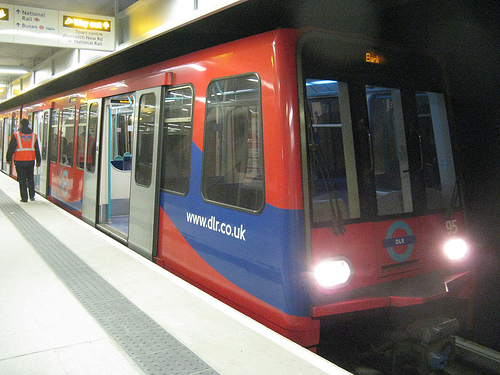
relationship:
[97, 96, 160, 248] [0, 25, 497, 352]
door open on subway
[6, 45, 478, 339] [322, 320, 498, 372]
subway on rail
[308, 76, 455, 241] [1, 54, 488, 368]
front window of train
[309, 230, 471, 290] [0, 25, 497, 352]
light in front of subway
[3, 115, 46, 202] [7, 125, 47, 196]
man wearing uniform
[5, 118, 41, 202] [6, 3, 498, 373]
man standing on station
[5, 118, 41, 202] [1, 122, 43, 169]
man wearing sweater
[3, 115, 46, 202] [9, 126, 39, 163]
man wearing vest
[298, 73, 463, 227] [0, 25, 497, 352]
front window on subway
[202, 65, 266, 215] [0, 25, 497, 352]
window on subway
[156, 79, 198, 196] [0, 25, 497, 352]
window on subway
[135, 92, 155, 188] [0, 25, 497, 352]
window on subway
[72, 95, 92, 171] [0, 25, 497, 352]
window on subway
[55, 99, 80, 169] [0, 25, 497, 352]
window on subway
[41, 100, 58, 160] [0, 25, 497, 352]
window on subway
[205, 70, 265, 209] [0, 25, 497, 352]
window on subway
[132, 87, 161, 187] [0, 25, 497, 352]
window on subway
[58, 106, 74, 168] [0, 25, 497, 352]
window on subway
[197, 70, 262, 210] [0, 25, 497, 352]
window on subway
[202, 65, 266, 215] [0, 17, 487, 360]
window on subway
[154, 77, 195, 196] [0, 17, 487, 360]
window on subway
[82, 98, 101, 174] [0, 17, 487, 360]
window on subway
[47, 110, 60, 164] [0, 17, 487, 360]
window on subway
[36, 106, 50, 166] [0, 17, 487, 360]
window on subway